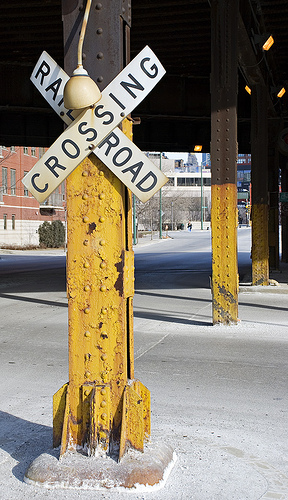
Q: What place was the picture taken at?
A: It was taken at the street.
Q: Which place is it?
A: It is a street.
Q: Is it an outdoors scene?
A: Yes, it is outdoors.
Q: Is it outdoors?
A: Yes, it is outdoors.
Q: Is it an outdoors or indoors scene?
A: It is outdoors.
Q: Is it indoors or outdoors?
A: It is outdoors.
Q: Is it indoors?
A: No, it is outdoors.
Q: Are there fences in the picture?
A: No, there are no fences.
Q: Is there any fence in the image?
A: No, there are no fences.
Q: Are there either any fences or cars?
A: No, there are no fences or cars.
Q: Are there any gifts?
A: No, there are no gifts.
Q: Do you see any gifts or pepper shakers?
A: No, there are no gifts or pepper shakers.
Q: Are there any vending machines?
A: No, there are no vending machines.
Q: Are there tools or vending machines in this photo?
A: No, there are no vending machines or tools.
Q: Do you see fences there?
A: No, there are no fences.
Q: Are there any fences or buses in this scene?
A: No, there are no fences or buses.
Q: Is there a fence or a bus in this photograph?
A: No, there are no fences or buses.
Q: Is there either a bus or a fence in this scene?
A: No, there are no fences or buses.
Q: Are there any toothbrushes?
A: No, there are no toothbrushes.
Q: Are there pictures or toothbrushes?
A: No, there are no toothbrushes or pictures.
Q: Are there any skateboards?
A: No, there are no skateboards.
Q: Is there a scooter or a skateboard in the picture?
A: No, there are no skateboards or scooters.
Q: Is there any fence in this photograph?
A: No, there are no fences.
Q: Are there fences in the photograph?
A: No, there are no fences.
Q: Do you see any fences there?
A: No, there are no fences.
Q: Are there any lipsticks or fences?
A: No, there are no fences or lipsticks.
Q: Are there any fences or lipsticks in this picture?
A: No, there are no fences or lipsticks.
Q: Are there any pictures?
A: No, there are no pictures.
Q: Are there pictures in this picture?
A: No, there are no pictures.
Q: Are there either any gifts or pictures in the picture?
A: No, there are no pictures or gifts.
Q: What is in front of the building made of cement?
A: The bush is in front of the building.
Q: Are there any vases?
A: No, there are no vases.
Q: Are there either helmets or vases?
A: No, there are no vases or helmets.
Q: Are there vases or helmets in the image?
A: No, there are no vases or helmets.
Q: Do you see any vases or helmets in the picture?
A: No, there are no vases or helmets.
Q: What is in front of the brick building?
A: The bush is in front of the building.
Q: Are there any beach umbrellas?
A: No, there are no beach umbrellas.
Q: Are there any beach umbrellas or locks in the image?
A: No, there are no beach umbrellas or locks.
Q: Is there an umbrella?
A: No, there are no umbrellas.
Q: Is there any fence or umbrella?
A: No, there are no umbrellas or fences.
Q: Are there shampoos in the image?
A: No, there are no shampoos.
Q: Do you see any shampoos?
A: No, there are no shampoos.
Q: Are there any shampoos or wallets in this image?
A: No, there are no shampoos or wallets.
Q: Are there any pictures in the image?
A: No, there are no pictures.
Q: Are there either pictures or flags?
A: No, there are no pictures or flags.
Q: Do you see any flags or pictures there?
A: No, there are no pictures or flags.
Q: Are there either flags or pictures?
A: No, there are no pictures or flags.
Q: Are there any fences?
A: No, there are no fences.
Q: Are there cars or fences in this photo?
A: No, there are no fences or cars.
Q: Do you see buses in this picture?
A: No, there are no buses.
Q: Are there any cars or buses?
A: No, there are no buses or cars.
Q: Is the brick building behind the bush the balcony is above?
A: Yes, the building is behind the shrub.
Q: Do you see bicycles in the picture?
A: No, there are no bicycles.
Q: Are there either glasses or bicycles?
A: No, there are no bicycles or glasses.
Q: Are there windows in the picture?
A: Yes, there is a window.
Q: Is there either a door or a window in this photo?
A: Yes, there is a window.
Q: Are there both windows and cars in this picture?
A: No, there is a window but no cars.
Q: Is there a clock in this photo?
A: No, there are no clocks.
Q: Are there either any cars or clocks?
A: No, there are no clocks or cars.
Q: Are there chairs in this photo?
A: No, there are no chairs.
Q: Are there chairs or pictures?
A: No, there are no chairs or pictures.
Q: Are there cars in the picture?
A: No, there are no cars.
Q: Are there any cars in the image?
A: No, there are no cars.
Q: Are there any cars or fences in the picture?
A: No, there are no cars or fences.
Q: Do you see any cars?
A: No, there are no cars.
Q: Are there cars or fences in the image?
A: No, there are no cars or fences.